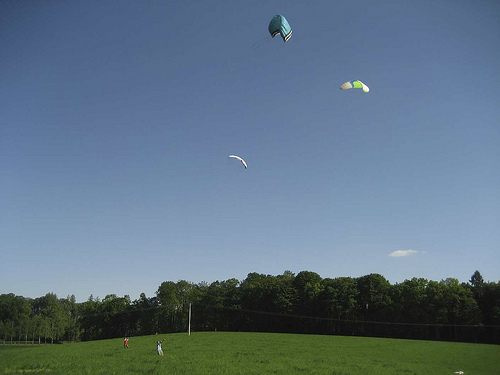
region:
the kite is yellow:
[322, 54, 410, 112]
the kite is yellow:
[336, 60, 407, 157]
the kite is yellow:
[333, 68, 388, 109]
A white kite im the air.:
[223, 146, 251, 174]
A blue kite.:
[259, 0, 296, 47]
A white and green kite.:
[340, 71, 378, 103]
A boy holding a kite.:
[153, 333, 170, 364]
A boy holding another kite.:
[117, 333, 135, 351]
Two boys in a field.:
[113, 330, 173, 362]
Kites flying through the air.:
[205, 3, 396, 195]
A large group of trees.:
[223, 259, 498, 347]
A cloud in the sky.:
[372, 236, 439, 268]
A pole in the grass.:
[183, 299, 197, 339]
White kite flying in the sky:
[222, 148, 266, 175]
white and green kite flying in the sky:
[331, 67, 378, 107]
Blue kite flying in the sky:
[265, 7, 307, 56]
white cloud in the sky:
[380, 239, 430, 263]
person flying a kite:
[151, 333, 171, 359]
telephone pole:
[178, 292, 199, 337]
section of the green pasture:
[246, 336, 328, 370]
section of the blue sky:
[70, 69, 145, 156]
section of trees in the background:
[3, 292, 80, 347]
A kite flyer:
[116, 331, 137, 352]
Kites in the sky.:
[158, 1, 433, 191]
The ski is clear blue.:
[61, 36, 197, 137]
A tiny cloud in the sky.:
[380, 230, 438, 265]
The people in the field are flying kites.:
[112, 3, 413, 364]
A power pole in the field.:
[180, 295, 200, 337]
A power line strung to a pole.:
[181, 293, 497, 336]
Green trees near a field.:
[5, 265, 495, 337]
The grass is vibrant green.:
[218, 335, 399, 373]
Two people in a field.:
[116, 321, 196, 366]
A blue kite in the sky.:
[252, 2, 310, 57]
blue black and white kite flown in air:
[269, 12, 294, 46]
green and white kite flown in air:
[339, 74, 371, 99]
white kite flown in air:
[224, 146, 251, 174]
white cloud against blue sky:
[383, 240, 419, 267]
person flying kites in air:
[151, 337, 170, 359]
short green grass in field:
[187, 340, 444, 365]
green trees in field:
[6, 300, 177, 330]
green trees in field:
[234, 288, 484, 332]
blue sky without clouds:
[8, 10, 219, 271]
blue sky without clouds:
[274, 95, 492, 237]